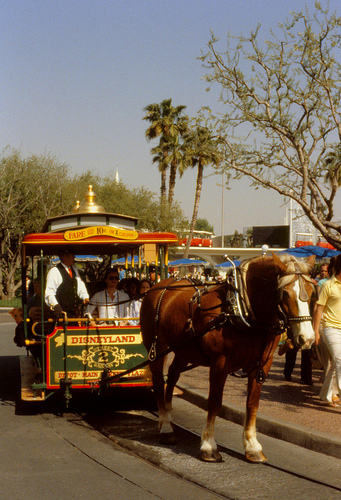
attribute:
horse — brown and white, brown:
[147, 257, 315, 458]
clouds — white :
[11, 16, 336, 194]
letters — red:
[72, 336, 136, 342]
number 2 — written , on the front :
[82, 329, 131, 375]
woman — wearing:
[311, 255, 339, 400]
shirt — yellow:
[317, 276, 339, 332]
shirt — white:
[87, 288, 129, 320]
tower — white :
[110, 166, 124, 188]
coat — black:
[50, 263, 85, 322]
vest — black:
[54, 265, 84, 319]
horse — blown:
[128, 251, 337, 475]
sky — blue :
[36, 41, 85, 77]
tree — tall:
[142, 96, 187, 224]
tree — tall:
[158, 133, 188, 216]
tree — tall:
[179, 126, 226, 261]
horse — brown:
[112, 225, 288, 417]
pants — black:
[283, 339, 314, 385]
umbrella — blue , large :
[167, 255, 205, 273]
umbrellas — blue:
[54, 253, 242, 272]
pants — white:
[318, 326, 339, 404]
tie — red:
[65, 264, 73, 276]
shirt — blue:
[316, 277, 330, 286]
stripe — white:
[293, 278, 315, 341]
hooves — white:
[197, 447, 265, 464]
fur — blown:
[135, 248, 323, 476]